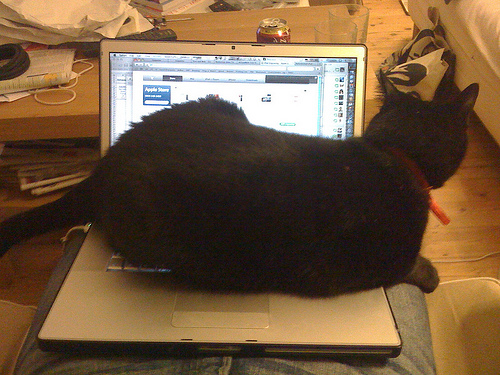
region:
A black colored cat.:
[0, 69, 479, 300]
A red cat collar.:
[384, 143, 453, 226]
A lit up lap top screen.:
[99, 40, 369, 164]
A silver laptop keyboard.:
[36, 218, 404, 357]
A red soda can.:
[255, 15, 294, 43]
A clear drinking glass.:
[313, 15, 360, 40]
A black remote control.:
[117, 25, 177, 40]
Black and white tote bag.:
[377, 5, 457, 105]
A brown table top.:
[0, 45, 101, 143]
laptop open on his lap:
[46, 25, 455, 357]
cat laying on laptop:
[25, 68, 457, 298]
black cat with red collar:
[57, 66, 482, 309]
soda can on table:
[243, 8, 301, 55]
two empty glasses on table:
[311, 5, 382, 67]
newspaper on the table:
[0, 39, 77, 99]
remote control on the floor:
[210, 2, 242, 21]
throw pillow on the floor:
[379, 25, 477, 100]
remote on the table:
[70, 18, 184, 54]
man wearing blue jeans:
[30, 236, 437, 373]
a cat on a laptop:
[2, 40, 499, 288]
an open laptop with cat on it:
[33, 26, 430, 373]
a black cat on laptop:
[23, 52, 485, 314]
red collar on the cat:
[372, 102, 486, 243]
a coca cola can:
[258, 15, 318, 67]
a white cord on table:
[23, 59, 113, 124]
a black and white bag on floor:
[367, 16, 474, 123]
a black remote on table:
[72, 27, 180, 67]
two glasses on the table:
[302, 2, 399, 74]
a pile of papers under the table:
[8, 147, 96, 225]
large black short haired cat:
[65, 78, 478, 304]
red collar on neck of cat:
[367, 134, 466, 244]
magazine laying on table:
[0, 45, 89, 95]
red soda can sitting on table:
[244, 16, 300, 43]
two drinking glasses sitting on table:
[307, 5, 373, 40]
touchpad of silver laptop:
[167, 284, 274, 331]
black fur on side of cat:
[177, 125, 317, 258]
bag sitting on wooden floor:
[381, 29, 453, 99]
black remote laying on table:
[76, 21, 186, 58]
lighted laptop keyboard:
[97, 258, 172, 279]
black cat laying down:
[77, 75, 467, 265]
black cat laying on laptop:
[70, 89, 469, 311]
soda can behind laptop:
[248, 10, 298, 48]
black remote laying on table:
[102, 26, 183, 53]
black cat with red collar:
[361, 113, 467, 233]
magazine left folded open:
[5, 45, 92, 102]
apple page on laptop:
[128, 69, 198, 113]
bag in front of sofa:
[385, 17, 467, 104]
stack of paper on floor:
[4, 140, 90, 196]